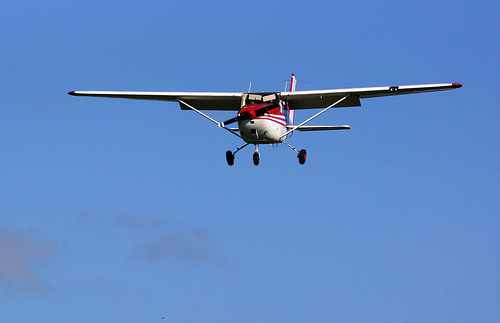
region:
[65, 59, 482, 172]
airplane flying in the sky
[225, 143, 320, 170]
landing gear with 3 wheels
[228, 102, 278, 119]
black propeller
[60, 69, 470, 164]
red, white, and blue airplane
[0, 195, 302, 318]
dark clouds in the sky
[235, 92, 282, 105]
two windows of an airplane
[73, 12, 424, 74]
clear, blue sky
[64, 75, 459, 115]
silver airplane wings with red distal ends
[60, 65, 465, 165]
flying, small engine airplane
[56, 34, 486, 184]
airplane flying in clear skies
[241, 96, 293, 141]
two red stripes on white plane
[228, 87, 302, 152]
red and white plane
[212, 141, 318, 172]
three black wheels of plane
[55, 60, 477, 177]
airplane with two wings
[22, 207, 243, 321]
grey wispy clouds in sky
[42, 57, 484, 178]
airplane in the air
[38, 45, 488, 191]
plane flying in the air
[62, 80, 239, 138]
white wing of a plane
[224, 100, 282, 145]
red nose of a plane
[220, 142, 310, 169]
three black tires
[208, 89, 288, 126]
the propellor on the plane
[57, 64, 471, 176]
the plane is in the sky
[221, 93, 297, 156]
the nose is red and silver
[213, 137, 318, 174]
3 wheels are for landing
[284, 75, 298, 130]
the tail is silver and red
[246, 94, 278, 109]
the pilots window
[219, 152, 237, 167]
the wheel is black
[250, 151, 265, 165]
this tire is in the middle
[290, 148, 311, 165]
this tire is on the side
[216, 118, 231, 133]
white stripes are at the edge of the propeller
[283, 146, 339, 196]
Plane has black wheel.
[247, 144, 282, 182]
Plane has black wheel.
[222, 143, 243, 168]
Plane has black wheel.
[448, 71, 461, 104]
Red tip on wing.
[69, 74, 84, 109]
Red tip on wing.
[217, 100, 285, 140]
Black propeller on front of plane.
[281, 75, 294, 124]
Red strip on tail of plane.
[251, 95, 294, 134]
Red stripes around mid section of plane.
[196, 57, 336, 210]
Plane is mostly white in color.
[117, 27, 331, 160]
Plane is flying in the sky.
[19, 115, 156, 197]
this is the sky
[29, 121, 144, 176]
the sky is blue in color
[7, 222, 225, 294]
the sky is full of clouds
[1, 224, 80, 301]
the clouds are white in color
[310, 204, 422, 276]
the sky is clear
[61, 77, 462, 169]
this is an airplane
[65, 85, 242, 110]
this is a wing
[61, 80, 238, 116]
the wing is long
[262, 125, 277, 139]
the airplane is white in color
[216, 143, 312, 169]
these are some wheels